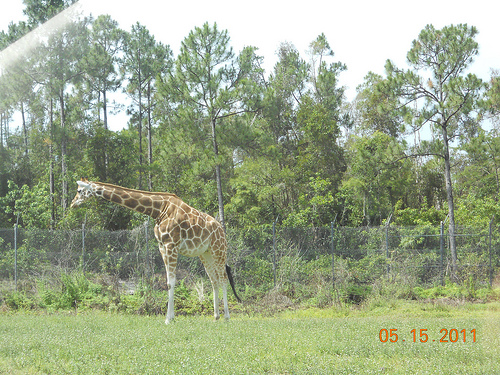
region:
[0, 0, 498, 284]
a large wooded area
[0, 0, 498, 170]
a large area of white sky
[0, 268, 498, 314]
a row of green shrubs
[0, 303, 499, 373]
a field of green grass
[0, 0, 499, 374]
a giraffe exhibit at a zoo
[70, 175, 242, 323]
a giraffe at the zoo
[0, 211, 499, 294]
a metal fence at the zoo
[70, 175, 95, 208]
the giraffe's head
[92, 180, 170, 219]
the giraffe's long neck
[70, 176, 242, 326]
a giraffe standing in an enclosure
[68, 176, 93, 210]
head of the giraffe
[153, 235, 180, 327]
the giraffe's front legs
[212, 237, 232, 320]
back legs of the giraffe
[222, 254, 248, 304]
long black tail of the giraffe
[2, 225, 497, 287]
metal fence of the enclosure behind the giraffe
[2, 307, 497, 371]
grass the giraffe is standing on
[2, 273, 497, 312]
low growing bushes along the bottom of the fence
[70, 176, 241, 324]
a giraffe with his head and neck bowing down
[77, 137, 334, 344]
the giraffe is tall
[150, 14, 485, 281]
the trees are taller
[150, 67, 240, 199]
the trees are skinny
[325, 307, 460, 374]
this is water marked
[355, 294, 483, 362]
the water mark is orange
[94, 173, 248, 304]
the giraffe is spotted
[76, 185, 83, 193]
The eye of the giraffe.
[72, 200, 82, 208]
The nose of the giraffe.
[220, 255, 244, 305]
The tail of the giraffe.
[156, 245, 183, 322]
The front legs of the giraffe.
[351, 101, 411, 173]
green leaves on the tree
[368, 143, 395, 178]
green leaves on the tree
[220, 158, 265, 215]
green leaves on the tree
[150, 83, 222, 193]
green leaves on the tree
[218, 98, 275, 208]
green leaves on the tree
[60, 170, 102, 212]
the giraffes head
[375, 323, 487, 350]
the date of the photo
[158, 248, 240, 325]
the giraffes legs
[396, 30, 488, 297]
a tree on the far right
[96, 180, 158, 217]
the long neck of the giraffe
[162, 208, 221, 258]
the body of the giraffe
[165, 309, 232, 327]
the feet of the giraffe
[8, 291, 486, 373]
the green grass below the giraffe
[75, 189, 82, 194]
the giraffes eyeball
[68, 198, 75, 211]
the giraffe's nose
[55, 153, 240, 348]
An animal in a field.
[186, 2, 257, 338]
A tree in the woods.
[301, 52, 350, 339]
A tree in the woods.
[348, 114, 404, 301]
A tree in the woods.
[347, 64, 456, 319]
A tree in the woods.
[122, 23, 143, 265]
A tree in the woods.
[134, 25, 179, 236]
A tree in the woods.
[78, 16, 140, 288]
A tree in the woods.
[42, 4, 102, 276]
A tree in the woods.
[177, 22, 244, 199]
A large tree with green leaves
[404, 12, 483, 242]
A large tree with green leaves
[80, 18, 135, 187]
A large tree with green leaves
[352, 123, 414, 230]
A large tree with green leaves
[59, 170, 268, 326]
A large giraffe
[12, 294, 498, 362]
A grassy open area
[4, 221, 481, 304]
A grey mesh fence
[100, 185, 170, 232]
A long neck of the giraffe